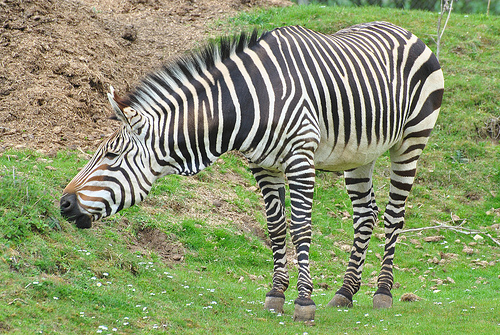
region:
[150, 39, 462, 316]
The zebra is standing in field.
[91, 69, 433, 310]
The zebra is black and white.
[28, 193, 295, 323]
Patches of dirt in the grass.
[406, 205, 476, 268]
A branch on the ground.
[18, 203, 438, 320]
The grass is green.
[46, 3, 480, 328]
this is a zebra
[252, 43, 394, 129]
black stripes on zebra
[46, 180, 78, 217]
black nose on zebra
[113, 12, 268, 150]
striped mane on zebra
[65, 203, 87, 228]
black mouth on zebra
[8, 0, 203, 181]
dirt mound in background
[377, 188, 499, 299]
sticks on the ground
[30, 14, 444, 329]
zebra has neck down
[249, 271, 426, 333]
grey feet on zebra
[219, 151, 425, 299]
black and white legs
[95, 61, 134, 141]
zebra has white ears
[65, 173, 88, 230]
zebra has black nose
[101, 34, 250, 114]
black and white mane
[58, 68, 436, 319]
zebra on green grass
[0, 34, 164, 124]
brown mulch behind zebra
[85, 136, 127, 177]
zebra has black eye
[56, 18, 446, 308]
A zebra standing in grass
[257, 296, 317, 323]
Front hooves on a zebra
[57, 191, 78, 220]
A black nose on a zebra's face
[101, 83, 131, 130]
Ears on a zebra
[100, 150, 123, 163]
An eye in a zebra's face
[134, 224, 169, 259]
A dirt hole near a zebra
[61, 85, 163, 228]
The head of a zebra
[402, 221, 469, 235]
A twig on the ground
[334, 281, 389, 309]
Back hooves on a zebra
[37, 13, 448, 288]
zebra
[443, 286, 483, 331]
short green and brown grass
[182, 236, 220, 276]
short green and brown grass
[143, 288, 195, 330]
short green and brown grass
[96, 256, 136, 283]
short green and brown grass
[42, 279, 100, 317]
short green and brown grass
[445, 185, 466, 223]
short green and brown grass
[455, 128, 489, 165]
short green and brown grass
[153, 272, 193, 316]
short green and yellow grass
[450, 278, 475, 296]
short green and yellow grass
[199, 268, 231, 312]
short green and yellow grass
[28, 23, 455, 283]
this is a zebra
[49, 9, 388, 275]
this is an animal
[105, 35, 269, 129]
the mane is striped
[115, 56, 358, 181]
the zebra is striped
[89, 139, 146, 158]
the eye is black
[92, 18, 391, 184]
the zebra is white and black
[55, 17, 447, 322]
zebra is bending down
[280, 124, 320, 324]
leg belongs to zebra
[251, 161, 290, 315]
leg belongs to zebra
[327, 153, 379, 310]
leg belongs to zebra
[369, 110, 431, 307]
leg belongs to zebra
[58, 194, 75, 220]
nose belongs to zebra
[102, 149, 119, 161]
eye belongs to zebra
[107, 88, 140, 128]
ear belongs to zebra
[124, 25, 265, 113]
mane belongs to zebra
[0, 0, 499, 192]
hill is behind zebra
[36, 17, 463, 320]
Zebra standing in the field